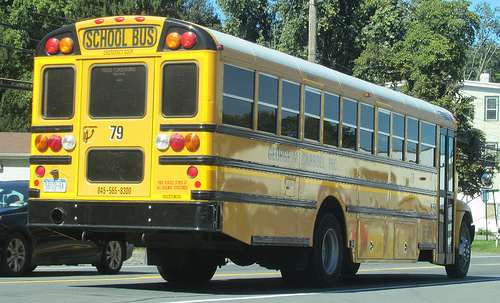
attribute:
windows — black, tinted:
[41, 59, 438, 171]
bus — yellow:
[26, 15, 475, 287]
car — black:
[0, 180, 133, 276]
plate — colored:
[42, 178, 66, 193]